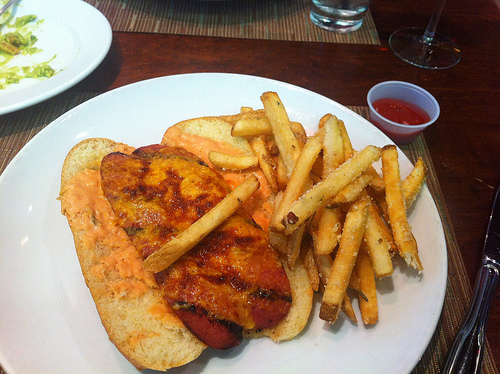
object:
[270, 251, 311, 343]
potato piece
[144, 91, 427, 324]
fries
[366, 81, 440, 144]
ketchup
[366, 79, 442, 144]
cup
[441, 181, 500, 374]
knife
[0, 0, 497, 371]
table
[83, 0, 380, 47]
placemat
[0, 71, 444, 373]
placemat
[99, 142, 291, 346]
meat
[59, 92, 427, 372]
bun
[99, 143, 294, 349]
cheese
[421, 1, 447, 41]
glass stem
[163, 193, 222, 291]
sauce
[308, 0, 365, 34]
glass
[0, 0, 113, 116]
plate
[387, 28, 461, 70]
bottom